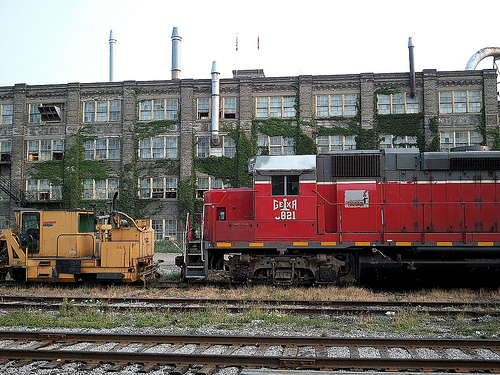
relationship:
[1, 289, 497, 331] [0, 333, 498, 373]
tracks in gravel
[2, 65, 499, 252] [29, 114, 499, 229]
building partially covered by kudzu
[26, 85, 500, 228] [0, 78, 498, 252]
green ivy growing up wall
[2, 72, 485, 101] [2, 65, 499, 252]
cornice on top of building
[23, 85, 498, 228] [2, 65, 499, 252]
green ivy on building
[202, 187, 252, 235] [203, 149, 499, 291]
engine on front of train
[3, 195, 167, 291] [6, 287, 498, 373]
machinery on train tracks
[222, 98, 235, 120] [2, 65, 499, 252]
window on building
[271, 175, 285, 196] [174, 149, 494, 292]
window on train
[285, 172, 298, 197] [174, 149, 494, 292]
window on train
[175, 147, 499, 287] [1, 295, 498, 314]
red train sitting on track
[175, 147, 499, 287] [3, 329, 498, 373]
red train sitting on track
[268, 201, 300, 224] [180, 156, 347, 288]
lettering on engine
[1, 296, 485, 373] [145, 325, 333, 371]
gravel between tracks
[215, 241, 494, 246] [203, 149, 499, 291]
line on train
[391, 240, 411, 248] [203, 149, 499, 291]
line on train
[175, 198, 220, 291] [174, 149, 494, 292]
stairs on train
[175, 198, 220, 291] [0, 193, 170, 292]
stairs on train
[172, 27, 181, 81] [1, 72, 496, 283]
stack above building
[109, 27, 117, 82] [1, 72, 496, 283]
stack above building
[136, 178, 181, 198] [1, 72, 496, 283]
windows on building